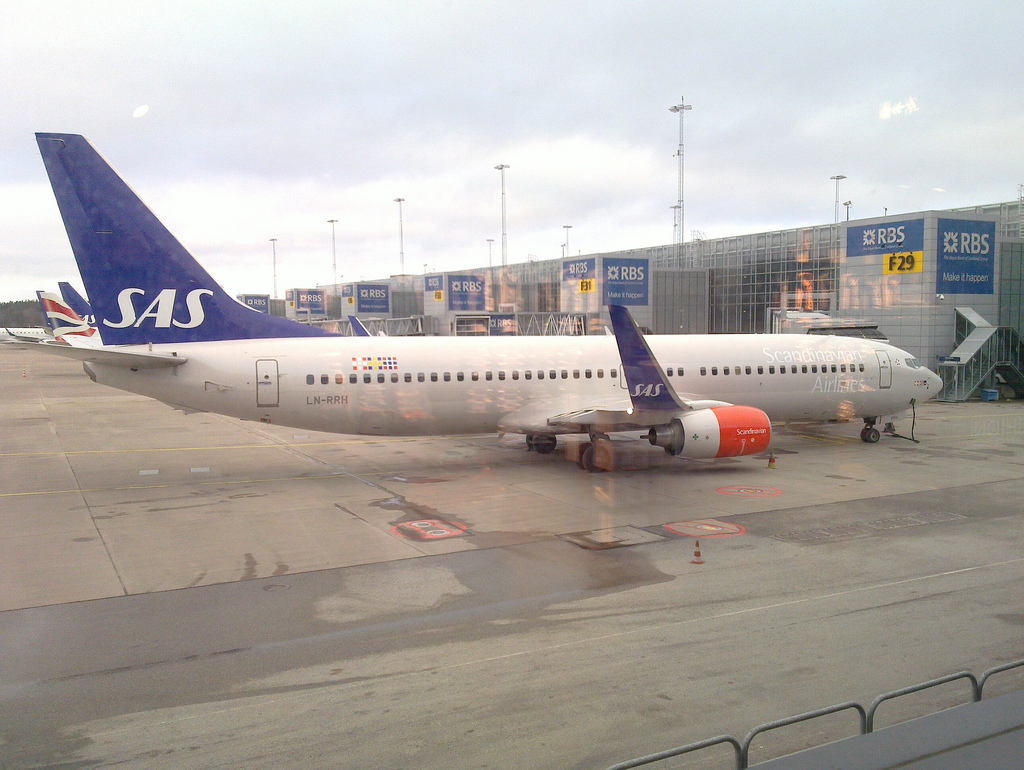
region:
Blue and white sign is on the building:
[599, 253, 653, 305]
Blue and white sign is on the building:
[444, 271, 486, 311]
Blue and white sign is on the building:
[421, 271, 442, 294]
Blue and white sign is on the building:
[349, 278, 392, 317]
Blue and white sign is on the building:
[285, 290, 293, 303]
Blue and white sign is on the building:
[241, 291, 271, 310]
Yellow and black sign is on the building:
[883, 249, 925, 275]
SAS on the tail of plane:
[92, 273, 228, 335]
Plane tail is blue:
[31, 117, 351, 355]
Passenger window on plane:
[293, 355, 883, 385]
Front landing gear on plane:
[850, 409, 889, 448]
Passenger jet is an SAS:
[21, 109, 958, 480]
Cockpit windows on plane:
[900, 354, 936, 371]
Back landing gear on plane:
[512, 411, 573, 466]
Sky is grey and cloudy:
[2, 2, 1023, 300]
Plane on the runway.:
[49, 106, 1007, 519]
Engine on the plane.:
[433, 269, 864, 529]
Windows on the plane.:
[314, 352, 492, 450]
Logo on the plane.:
[43, 207, 370, 443]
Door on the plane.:
[766, 286, 960, 432]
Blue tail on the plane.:
[52, 99, 353, 413]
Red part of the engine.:
[669, 380, 826, 510]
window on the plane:
[285, 373, 315, 392]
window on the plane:
[326, 373, 340, 384]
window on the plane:
[365, 377, 381, 388]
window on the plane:
[602, 370, 623, 380]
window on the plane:
[896, 354, 920, 375]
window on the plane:
[826, 364, 850, 378]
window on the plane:
[725, 367, 729, 378]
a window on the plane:
[348, 341, 380, 367]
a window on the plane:
[394, 367, 429, 390]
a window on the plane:
[447, 347, 449, 382]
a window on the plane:
[403, 358, 426, 393]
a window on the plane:
[441, 353, 461, 379]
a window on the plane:
[491, 364, 514, 390]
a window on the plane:
[544, 358, 573, 384]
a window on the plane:
[476, 350, 522, 396]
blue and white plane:
[111, 164, 971, 538]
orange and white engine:
[620, 316, 833, 485]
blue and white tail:
[26, 143, 303, 441]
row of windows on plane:
[283, 322, 847, 412]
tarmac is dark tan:
[14, 632, 192, 737]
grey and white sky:
[315, 0, 487, 169]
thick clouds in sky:
[254, 23, 572, 128]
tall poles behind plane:
[172, 108, 762, 304]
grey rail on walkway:
[766, 682, 1000, 766]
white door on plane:
[863, 333, 906, 400]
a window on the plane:
[333, 361, 385, 393]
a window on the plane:
[468, 297, 488, 381]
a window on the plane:
[509, 355, 535, 381]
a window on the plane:
[409, 353, 458, 405]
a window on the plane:
[529, 358, 555, 393]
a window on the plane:
[456, 326, 514, 404]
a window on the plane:
[497, 353, 535, 423]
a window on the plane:
[254, 347, 294, 387]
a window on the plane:
[292, 358, 370, 425]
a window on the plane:
[468, 347, 523, 434]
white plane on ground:
[20, 98, 956, 484]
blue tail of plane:
[17, 98, 221, 340]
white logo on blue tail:
[117, 262, 219, 338]